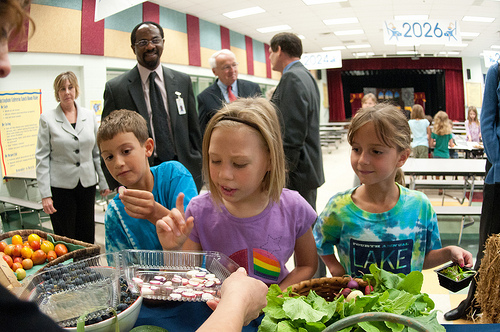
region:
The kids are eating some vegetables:
[38, 77, 461, 317]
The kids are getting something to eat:
[58, 91, 453, 308]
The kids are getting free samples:
[71, 97, 451, 303]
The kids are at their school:
[67, 87, 459, 308]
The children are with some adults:
[35, 16, 451, 316]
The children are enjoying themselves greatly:
[40, 16, 451, 303]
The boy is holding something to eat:
[96, 112, 153, 247]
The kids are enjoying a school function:
[12, 36, 487, 322]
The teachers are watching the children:
[17, 15, 438, 312]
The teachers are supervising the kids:
[22, 23, 473, 320]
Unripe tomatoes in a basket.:
[0, 228, 67, 278]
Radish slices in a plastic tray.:
[128, 267, 225, 301]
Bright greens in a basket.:
[290, 288, 430, 328]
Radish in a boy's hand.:
[118, 187, 124, 197]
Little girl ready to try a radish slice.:
[156, 101, 316, 291]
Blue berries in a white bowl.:
[37, 263, 135, 323]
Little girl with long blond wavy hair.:
[432, 112, 452, 136]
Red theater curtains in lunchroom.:
[329, 56, 462, 125]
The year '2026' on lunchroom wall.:
[401, 23, 445, 37]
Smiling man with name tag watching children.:
[98, 22, 199, 186]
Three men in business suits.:
[106, 17, 345, 185]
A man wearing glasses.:
[123, 13, 170, 75]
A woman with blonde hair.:
[34, 65, 108, 237]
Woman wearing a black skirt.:
[31, 73, 108, 242]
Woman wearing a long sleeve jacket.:
[28, 68, 107, 198]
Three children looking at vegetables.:
[88, 100, 450, 292]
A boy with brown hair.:
[85, 105, 175, 195]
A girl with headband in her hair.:
[196, 83, 288, 209]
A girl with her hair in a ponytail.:
[343, 98, 415, 200]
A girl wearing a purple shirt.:
[187, 101, 312, 281]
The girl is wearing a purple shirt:
[184, 190, 316, 281]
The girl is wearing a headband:
[210, 115, 272, 127]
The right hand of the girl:
[158, 193, 192, 247]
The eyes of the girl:
[209, 154, 249, 166]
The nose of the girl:
[218, 164, 233, 179]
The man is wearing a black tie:
[146, 72, 177, 159]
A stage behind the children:
[328, 58, 464, 121]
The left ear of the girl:
[396, 147, 411, 164]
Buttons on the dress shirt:
[71, 131, 84, 171]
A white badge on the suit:
[173, 90, 185, 116]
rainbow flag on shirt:
[243, 242, 279, 279]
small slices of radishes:
[136, 266, 222, 288]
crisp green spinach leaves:
[285, 275, 395, 322]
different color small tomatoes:
[4, 219, 69, 259]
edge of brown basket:
[296, 275, 356, 290]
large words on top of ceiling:
[373, 13, 465, 50]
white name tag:
[166, 83, 188, 118]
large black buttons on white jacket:
[61, 128, 92, 177]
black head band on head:
[203, 106, 279, 131]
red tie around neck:
[220, 83, 246, 104]